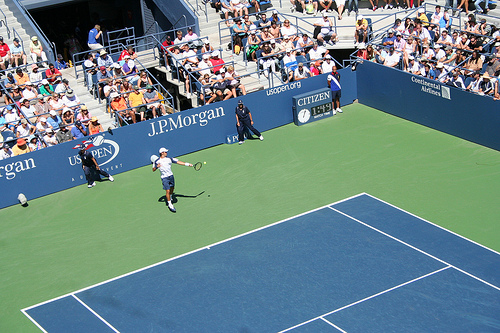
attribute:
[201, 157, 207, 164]
ball — flying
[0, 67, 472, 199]
wall — blue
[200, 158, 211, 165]
ball — flying, tennis ball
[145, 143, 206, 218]
shirt — blue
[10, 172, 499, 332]
tennis court — green , blue 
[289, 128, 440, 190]
court — green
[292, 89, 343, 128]
clock — Official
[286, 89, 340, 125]
clock — round, white, analog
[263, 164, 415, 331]
court — blue, green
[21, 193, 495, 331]
tennis court — blue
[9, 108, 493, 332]
field — green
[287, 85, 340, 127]
clock — blue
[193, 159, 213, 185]
tennis ball — small, green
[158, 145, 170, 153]
hat — white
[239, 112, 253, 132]
clothes — black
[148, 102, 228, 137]
advertisement — J.P. Morgan